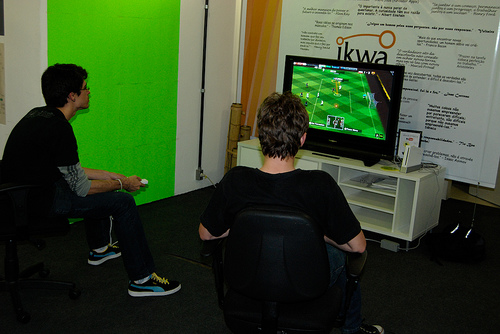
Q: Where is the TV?
A: In front of the kids.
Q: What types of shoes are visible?
A: Puma.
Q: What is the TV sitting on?
A: A shelf.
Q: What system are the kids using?
A: Wii.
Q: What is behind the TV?
A: A poster.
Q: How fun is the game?
A: Very fun.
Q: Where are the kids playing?
A: In a room.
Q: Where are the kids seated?
A: In a room.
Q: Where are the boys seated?
A: In front of the TV.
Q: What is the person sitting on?
A: Black swivel chairs for gaming.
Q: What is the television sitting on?
A: Entertainment system stand, furniture.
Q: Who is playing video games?
A: Two boys wearing black.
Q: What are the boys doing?
A: Playing video games.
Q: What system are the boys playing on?
A: Wii.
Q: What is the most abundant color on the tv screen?
A: Green.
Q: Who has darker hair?
A: Boy to the left.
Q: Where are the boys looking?
A: At the TV.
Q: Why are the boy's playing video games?
A: For fun.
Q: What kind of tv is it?
A: Flat screen.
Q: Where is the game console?
A: Beside the TV.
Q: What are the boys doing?
A: Playing a video game.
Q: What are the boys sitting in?
A: Chairs.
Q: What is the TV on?
A: A TV stand.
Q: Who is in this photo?
A: Two men.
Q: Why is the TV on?
A: The men are playing a game.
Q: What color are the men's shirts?
A: Black.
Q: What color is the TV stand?
A: White.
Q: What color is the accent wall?
A: Neon green.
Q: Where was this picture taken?
A: A game room.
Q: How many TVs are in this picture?
A: One.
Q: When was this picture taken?
A: During the day.